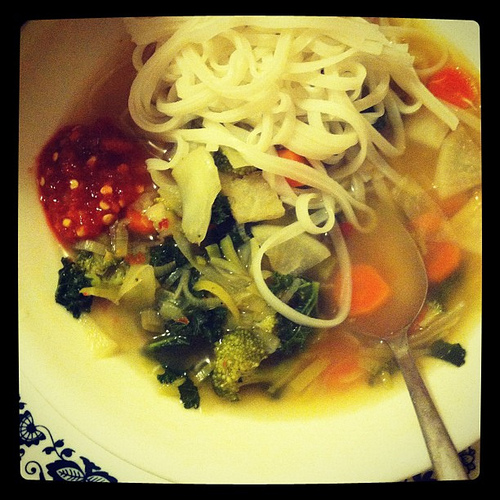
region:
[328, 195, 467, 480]
a silver metal spoon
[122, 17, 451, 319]
a pile of white noodles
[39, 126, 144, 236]
red seeded sauce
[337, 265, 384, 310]
an orange piece of carrot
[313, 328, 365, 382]
an orange piece of carrot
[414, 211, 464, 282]
an orange piece of carrot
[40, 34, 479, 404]
a bowl of vegetable soup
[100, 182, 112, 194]
a seed in sauce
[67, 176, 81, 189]
a seed in sauce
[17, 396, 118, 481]
a blue pattern on the bowl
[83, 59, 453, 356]
A bowl of soup.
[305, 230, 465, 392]
The spoon is in the soup.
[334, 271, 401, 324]
The spoon has a piece of carrot on it.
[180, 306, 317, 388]
The green broccoli in the soup.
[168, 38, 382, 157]
White noodles on top of the soup.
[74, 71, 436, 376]
Food in a white bow.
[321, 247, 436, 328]
The carrot is orange.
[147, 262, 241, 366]
The soup has kale in it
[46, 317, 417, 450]
The bowl is white.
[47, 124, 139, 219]
Seeds in the red sauce.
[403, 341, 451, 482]
this is a spoon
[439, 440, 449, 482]
the spoon is metallic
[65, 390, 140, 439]
this is a plate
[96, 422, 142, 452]
the plate is white in color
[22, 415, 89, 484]
the plate has some decorations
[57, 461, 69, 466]
the decorations are black in color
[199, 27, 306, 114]
this is some spaghetti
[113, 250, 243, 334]
the spices are green in color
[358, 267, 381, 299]
this is a carrot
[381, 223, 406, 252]
this is some soup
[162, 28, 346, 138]
this is spaghetti on the plate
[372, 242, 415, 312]
the food has soup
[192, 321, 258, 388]
this is broccoli on the plate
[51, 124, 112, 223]
the tomato is red in color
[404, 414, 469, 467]
this is a spoon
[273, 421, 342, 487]
this is a plate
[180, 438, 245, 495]
the plate is white in color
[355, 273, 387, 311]
this is acarrot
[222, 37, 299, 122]
the spaghetti is white in color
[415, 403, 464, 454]
the spoon is metallic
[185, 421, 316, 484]
the plate is white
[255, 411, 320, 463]
the plate is white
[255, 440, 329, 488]
the plate is white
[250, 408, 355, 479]
the plate is white